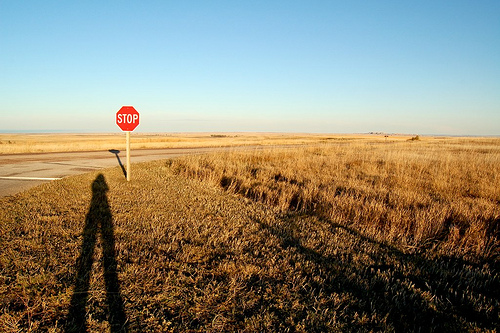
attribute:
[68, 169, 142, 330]
shadow — woman, long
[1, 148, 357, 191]
road — grey, paved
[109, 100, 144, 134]
sign — red, white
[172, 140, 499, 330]
field — brown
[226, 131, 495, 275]
grass — golden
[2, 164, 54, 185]
line — white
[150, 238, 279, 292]
shadow — black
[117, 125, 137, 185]
pole — tall, brown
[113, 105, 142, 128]
sign — red, large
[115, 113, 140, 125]
words — white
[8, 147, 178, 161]
dirt — brown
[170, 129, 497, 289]
grass — brown, tall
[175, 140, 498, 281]
grass — tall, brown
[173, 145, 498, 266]
grass — brown, tall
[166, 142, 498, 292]
grass — tall, brown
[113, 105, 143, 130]
stop sign — red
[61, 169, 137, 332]
shadow — person, long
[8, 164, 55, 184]
line — white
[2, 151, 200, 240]
road — paved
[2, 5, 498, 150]
sky — blue, cloudless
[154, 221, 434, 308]
field — tan, brown, grassy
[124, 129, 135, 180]
pole — small, wooden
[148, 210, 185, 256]
grass — tall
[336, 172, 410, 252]
hay — brown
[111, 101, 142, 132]
sign — stop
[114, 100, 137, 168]
sign — stop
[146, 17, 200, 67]
sky — clear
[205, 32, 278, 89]
sky — clear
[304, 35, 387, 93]
sky — clear, blue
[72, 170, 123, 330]
shadow — tall, black, person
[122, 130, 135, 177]
pole — grey, metal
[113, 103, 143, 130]
sign — red, white, stop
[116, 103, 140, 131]
sign — stop, octagon, white, red